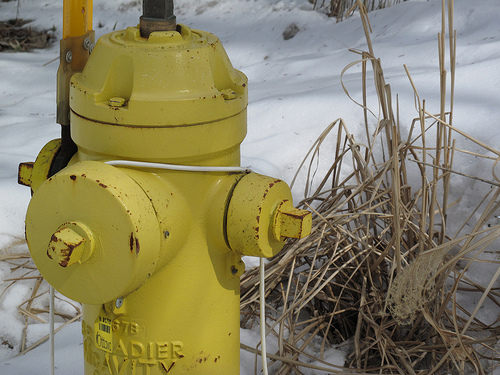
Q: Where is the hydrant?
A: In snow.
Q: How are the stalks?
A: Dead.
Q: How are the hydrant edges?
A: Worn.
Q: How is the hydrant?
A: Rusty.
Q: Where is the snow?
A: On ground.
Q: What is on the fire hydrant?
A: Yellow paint.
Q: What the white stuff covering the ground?
A: Snow.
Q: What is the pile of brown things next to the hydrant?
A: Sticks.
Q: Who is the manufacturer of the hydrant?
A: Adier.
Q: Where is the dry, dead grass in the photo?
A: Near a fire hydrant.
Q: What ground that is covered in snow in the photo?
A: Ground beside the yellow hydrant.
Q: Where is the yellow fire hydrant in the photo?
A: Fire hydrant in the snow.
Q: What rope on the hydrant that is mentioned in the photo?
A: The white rope.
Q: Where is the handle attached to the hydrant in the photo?
A: Left of hydrant.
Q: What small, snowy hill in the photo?
A: Hill near brown grass.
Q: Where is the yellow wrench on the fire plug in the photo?
A: Top of hydrant.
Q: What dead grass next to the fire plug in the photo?
A: Dead grass in the snow.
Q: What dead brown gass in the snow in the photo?
A: Gress near fire plug.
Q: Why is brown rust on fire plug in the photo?
A: Fire plug needs painting.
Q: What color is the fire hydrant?
A: Yellow.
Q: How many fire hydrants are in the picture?
A: One.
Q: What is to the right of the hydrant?
A: Dead shrub.